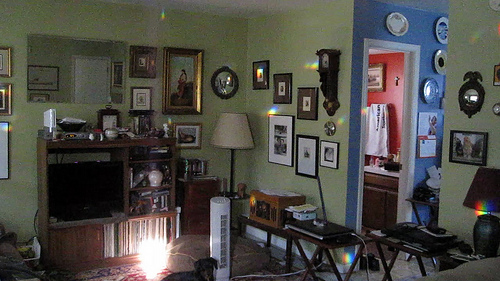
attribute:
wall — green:
[220, 14, 350, 48]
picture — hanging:
[320, 139, 340, 169]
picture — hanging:
[297, 134, 320, 177]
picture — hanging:
[267, 113, 294, 168]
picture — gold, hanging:
[161, 45, 203, 114]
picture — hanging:
[174, 121, 202, 149]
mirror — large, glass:
[25, 33, 126, 104]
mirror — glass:
[458, 71, 484, 118]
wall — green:
[437, 3, 497, 248]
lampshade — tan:
[211, 111, 253, 149]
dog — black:
[162, 256, 218, 280]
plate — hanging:
[387, 10, 410, 37]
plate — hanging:
[435, 16, 448, 44]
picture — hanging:
[449, 130, 489, 167]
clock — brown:
[316, 49, 342, 118]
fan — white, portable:
[209, 195, 326, 279]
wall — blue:
[347, 1, 448, 265]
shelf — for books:
[178, 177, 219, 237]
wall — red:
[367, 53, 402, 169]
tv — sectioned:
[48, 160, 125, 220]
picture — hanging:
[129, 44, 158, 78]